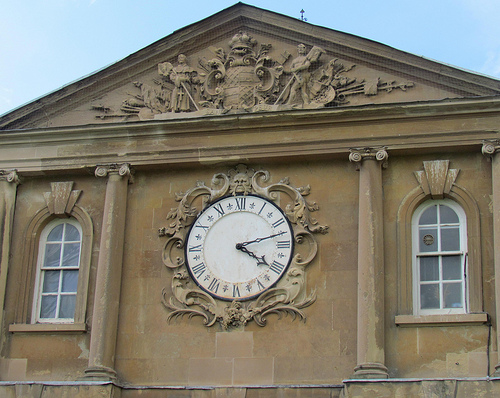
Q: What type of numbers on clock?
A: Roman.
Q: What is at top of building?
A: A scene.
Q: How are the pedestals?
A: Concrete.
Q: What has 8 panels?
A: Window.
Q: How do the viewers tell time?
A: By the hands.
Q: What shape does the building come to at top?
A: Triangle.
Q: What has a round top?
A: Window.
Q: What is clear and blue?
A: Sky.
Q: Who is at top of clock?
A: A man.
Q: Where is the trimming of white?
A: Windows.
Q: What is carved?
A: Pillars.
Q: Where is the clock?
A: On the building.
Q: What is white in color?
A: Clock.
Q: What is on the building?
A: Clock.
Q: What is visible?
A: Clock.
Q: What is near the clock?
A: Windows.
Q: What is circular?
A: Clock.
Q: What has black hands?
A: Clock.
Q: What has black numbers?
A: Clock.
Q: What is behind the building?
A: Sky.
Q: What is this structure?
A: Building.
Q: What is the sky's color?
A: Blue.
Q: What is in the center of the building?
A: Clock.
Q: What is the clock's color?
A: White.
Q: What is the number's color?
A: Black.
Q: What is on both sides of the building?
A: Windows.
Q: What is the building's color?
A: Tan.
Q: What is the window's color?
A: White.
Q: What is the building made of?
A: Stone.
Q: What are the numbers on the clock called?
A: Roman numerals.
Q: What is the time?
A: 4:20.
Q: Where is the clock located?
A: On the front of a building.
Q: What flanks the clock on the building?
A: Windows.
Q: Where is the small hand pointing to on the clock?
A: Four.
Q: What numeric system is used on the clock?
A: Roman numerals.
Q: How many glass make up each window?
A: Eight.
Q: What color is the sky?
A: Blue.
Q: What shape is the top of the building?
A: Triangle.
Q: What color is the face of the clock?
A: White.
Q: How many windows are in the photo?
A: Two.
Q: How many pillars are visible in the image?
A: Two.